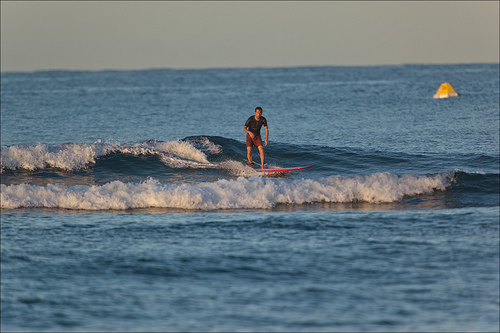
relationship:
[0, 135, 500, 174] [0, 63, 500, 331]
waves on blue water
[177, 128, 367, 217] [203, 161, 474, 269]
light on waves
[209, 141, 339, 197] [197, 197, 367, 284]
surfboard in water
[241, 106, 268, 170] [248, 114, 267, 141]
surfer wearing a shirt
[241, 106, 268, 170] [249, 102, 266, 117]
surfer with hair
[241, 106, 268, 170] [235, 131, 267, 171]
surfer in shorts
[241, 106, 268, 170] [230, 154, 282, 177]
surfer on surfboard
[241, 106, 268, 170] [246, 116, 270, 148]
surfer in shirt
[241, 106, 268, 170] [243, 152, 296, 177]
surfer on surfboard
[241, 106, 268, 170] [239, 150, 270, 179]
surfer on surfboard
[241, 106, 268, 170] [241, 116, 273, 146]
surfer in shirt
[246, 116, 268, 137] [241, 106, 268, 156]
shirt on man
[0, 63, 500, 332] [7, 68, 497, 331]
ripples in water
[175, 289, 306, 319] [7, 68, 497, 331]
ripples in water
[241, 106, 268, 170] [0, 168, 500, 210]
surfer riding wave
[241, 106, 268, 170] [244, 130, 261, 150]
surfer wearing trunks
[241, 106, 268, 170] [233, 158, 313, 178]
surfer riding surfboard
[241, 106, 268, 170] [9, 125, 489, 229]
surfer prepares for waves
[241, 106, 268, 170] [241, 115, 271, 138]
surfer wearing top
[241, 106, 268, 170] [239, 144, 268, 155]
surfer bends knees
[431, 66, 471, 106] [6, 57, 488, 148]
buoy in distance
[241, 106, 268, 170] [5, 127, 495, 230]
surfer catching wave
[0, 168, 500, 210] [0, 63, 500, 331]
wave in blue water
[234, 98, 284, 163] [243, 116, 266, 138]
surfer with shirt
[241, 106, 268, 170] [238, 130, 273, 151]
surfer with shorts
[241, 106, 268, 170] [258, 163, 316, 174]
surfer with surfboard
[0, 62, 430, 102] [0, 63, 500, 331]
horizon on blue water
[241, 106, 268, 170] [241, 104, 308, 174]
surfer practicing sport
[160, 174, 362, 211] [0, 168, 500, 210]
reflection of wave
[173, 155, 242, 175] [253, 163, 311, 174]
wake from surfboard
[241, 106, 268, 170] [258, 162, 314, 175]
surfer on surfboard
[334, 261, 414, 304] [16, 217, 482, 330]
part of blue water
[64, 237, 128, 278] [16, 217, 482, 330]
part of blue water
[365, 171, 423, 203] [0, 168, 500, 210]
part of wave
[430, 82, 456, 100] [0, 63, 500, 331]
yellow boat in middle of blue water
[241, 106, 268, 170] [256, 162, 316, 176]
surfer on surf board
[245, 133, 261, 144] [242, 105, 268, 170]
brown shorts on man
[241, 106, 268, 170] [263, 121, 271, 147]
surfer has arm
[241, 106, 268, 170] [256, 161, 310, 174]
surfer riding surfboard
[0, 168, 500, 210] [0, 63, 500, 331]
wave on blue water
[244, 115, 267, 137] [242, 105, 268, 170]
shirt on man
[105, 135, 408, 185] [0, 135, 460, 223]
shadow on waves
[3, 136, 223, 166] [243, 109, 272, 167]
waves behind surfer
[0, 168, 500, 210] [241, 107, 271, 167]
wave infront of surfer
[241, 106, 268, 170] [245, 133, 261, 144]
surfer wearing brown shorts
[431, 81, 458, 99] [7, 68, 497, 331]
buoy in water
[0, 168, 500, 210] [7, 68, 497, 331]
wave in water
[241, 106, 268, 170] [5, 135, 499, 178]
surfer riding wave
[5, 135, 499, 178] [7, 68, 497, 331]
wave in water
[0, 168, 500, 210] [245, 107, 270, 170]
wave in front of surfer